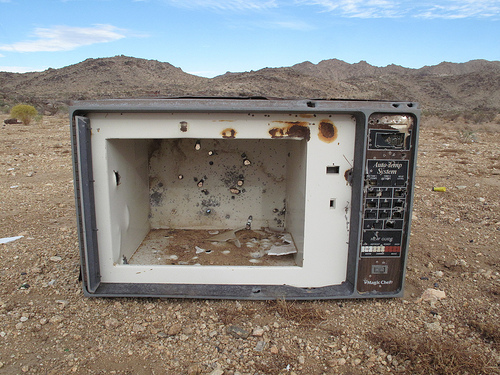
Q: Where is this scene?
A: Desert.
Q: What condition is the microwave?
A: Decrepid.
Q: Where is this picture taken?
A: A desert.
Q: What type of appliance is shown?
A: A microwave.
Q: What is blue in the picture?
A: The sky.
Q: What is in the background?
A: Hills.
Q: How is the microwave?
A: Rusted out.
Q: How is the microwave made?
A: Of metal.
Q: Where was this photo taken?
A: In a desert.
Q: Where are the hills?
A: Behind oven.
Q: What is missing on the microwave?
A: Door.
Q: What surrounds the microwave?
A: Dirt.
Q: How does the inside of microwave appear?
A: Dirty.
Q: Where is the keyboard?
A: Right side.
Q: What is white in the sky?
A: Clouds.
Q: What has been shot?
A: Microwave.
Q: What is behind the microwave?
A: Mountains.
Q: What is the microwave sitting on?
A: Dirt.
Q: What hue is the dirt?
A: Brown.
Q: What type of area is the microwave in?
A: Desert.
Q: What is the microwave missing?
A: Door.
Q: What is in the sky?
A: Clouds.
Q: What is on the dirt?
A: Rocks.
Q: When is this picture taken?
A: Daytime.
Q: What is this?
A: Microwave.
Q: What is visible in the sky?
A: Clouds.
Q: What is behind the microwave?
A: Small hills.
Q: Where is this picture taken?
A: Desert.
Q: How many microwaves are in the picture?
A: One.